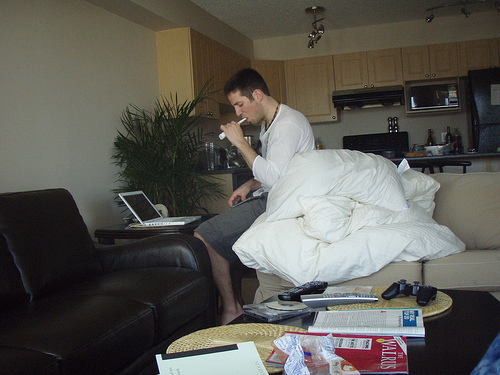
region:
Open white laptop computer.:
[115, 187, 202, 232]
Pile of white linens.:
[230, 147, 469, 286]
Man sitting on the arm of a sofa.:
[201, 66, 316, 330]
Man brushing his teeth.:
[192, 63, 318, 331]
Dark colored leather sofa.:
[0, 186, 222, 374]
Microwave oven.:
[402, 76, 459, 113]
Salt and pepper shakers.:
[383, 113, 401, 133]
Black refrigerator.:
[465, 63, 499, 152]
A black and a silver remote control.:
[276, 274, 380, 311]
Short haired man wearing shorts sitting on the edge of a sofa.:
[190, 66, 315, 325]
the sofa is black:
[27, 191, 150, 362]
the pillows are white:
[271, 147, 426, 276]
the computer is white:
[107, 176, 209, 241]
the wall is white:
[27, 33, 94, 143]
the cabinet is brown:
[298, 57, 338, 125]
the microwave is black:
[399, 78, 470, 123]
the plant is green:
[115, 97, 218, 209]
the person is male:
[185, 57, 330, 322]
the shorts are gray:
[189, 182, 289, 266]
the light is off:
[285, 6, 339, 58]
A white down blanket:
[300, 170, 417, 248]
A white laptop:
[121, 184, 192, 231]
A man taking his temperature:
[220, 76, 291, 216]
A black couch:
[17, 191, 145, 346]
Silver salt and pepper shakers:
[382, 110, 408, 135]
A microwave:
[408, 76, 463, 116]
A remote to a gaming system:
[396, 271, 436, 309]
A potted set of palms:
[130, 106, 218, 201]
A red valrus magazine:
[286, 322, 408, 374]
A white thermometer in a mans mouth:
[219, 116, 250, 140]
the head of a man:
[223, 65, 273, 131]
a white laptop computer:
[116, 187, 206, 227]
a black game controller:
[378, 275, 439, 309]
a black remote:
[276, 275, 331, 305]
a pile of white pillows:
[228, 142, 472, 291]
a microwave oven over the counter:
[402, 74, 463, 113]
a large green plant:
[106, 72, 229, 217]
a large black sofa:
[0, 183, 224, 373]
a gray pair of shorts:
[190, 190, 270, 263]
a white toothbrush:
[217, 114, 249, 142]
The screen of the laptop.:
[118, 187, 163, 223]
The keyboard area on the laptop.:
[153, 207, 200, 228]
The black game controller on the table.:
[384, 276, 438, 303]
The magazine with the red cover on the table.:
[281, 331, 403, 373]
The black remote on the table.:
[276, 270, 332, 308]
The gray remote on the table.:
[299, 286, 378, 308]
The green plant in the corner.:
[118, 98, 222, 216]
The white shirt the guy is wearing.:
[252, 112, 312, 187]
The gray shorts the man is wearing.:
[192, 188, 267, 252]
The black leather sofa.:
[1, 176, 223, 368]